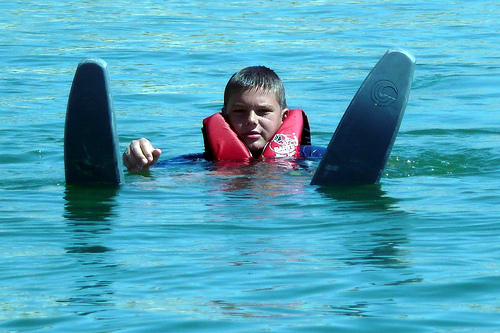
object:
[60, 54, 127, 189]
boards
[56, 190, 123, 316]
reflection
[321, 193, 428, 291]
reflection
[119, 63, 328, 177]
boy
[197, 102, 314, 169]
vest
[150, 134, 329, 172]
shirt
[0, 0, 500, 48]
water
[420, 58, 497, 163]
water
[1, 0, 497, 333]
ocean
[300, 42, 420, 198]
flipper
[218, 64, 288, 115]
hair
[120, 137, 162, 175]
hand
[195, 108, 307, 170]
life guard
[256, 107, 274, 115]
eye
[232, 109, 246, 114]
eye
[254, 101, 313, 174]
side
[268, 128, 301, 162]
design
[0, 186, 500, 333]
waters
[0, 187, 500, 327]
water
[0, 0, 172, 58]
sunny day